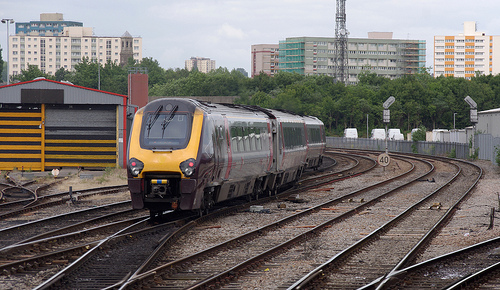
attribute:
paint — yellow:
[131, 108, 204, 175]